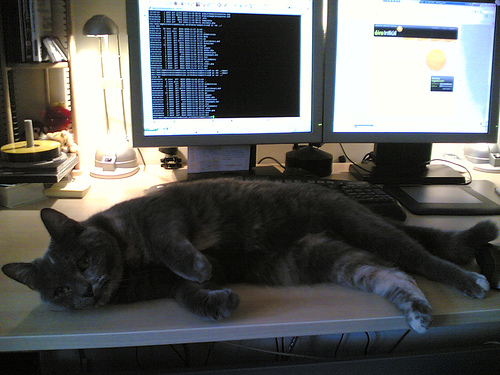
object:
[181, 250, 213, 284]
paws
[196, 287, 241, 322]
paws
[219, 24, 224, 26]
letters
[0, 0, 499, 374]
background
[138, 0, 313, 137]
screen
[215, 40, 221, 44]
lettering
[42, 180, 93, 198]
paper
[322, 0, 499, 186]
computer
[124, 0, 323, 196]
computer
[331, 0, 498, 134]
screen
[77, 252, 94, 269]
eyes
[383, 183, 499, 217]
mouse pad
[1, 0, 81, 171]
shelf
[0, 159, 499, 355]
cat desk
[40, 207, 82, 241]
ear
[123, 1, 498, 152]
monitors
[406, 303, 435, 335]
foot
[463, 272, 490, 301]
foot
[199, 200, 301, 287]
belly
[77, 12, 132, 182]
open water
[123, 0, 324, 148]
computer monitor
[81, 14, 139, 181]
desk lamp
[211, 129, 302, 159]
floor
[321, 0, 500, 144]
monitors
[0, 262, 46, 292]
ear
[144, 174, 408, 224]
keyboard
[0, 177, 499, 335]
cat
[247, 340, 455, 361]
cords